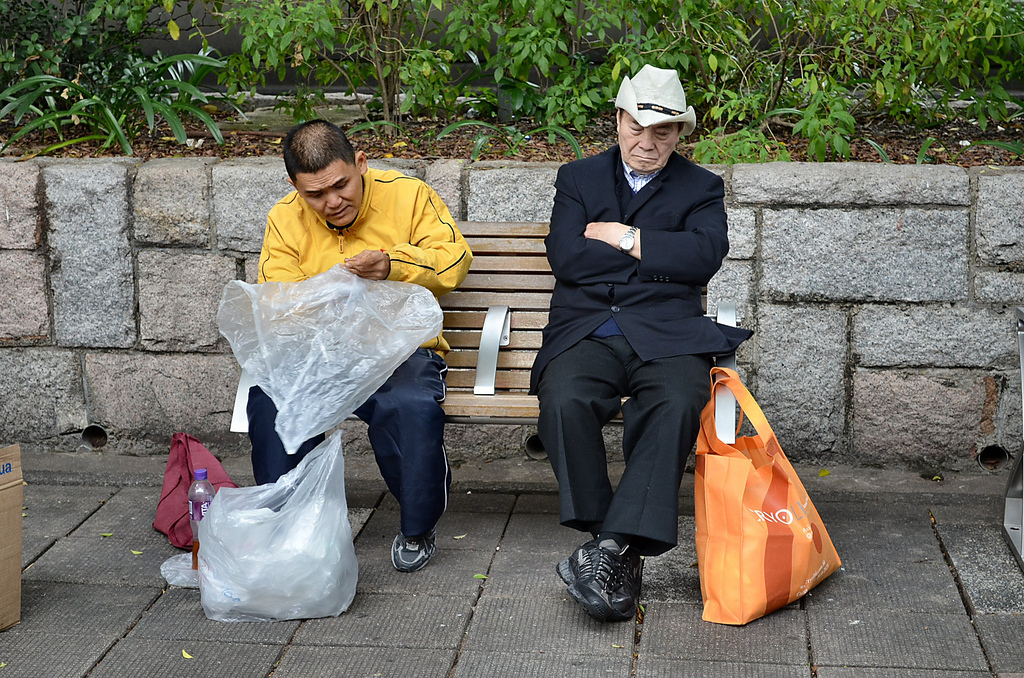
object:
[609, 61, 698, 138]
hat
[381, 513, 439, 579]
shoes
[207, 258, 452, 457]
bag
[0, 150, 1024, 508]
wall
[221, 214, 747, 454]
bench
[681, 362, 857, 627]
bag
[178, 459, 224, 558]
bottle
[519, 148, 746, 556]
suit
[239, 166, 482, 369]
shirt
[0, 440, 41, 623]
box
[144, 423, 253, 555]
bag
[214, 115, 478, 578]
man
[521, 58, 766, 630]
man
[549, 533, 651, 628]
sneakers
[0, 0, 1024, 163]
hedges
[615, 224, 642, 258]
watch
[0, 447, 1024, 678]
ground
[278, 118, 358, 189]
hair